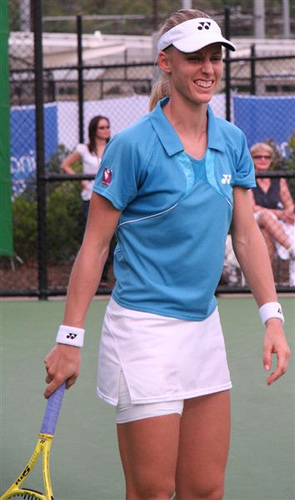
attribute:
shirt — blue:
[89, 93, 258, 322]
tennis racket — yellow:
[1, 379, 65, 498]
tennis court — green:
[3, 294, 291, 498]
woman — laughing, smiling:
[41, 7, 292, 498]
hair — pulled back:
[139, 6, 214, 117]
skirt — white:
[96, 301, 233, 408]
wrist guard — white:
[55, 324, 85, 349]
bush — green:
[15, 151, 86, 258]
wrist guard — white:
[258, 302, 284, 327]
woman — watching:
[251, 142, 294, 270]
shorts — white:
[115, 379, 184, 424]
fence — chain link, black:
[4, 0, 293, 291]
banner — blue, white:
[7, 92, 292, 202]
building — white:
[8, 28, 293, 106]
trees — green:
[15, 144, 93, 261]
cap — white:
[158, 14, 238, 57]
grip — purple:
[39, 383, 66, 431]